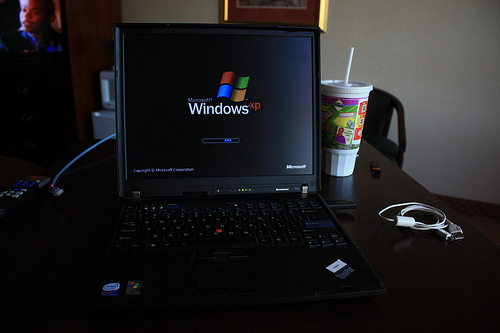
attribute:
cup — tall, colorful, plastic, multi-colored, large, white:
[326, 44, 367, 178]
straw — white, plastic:
[341, 47, 356, 80]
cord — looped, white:
[381, 205, 462, 243]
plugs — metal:
[445, 233, 461, 241]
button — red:
[215, 229, 222, 234]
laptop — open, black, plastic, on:
[84, 26, 386, 302]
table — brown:
[3, 139, 499, 330]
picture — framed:
[240, 2, 306, 7]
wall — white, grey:
[335, 1, 493, 200]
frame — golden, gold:
[223, 4, 329, 33]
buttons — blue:
[12, 178, 35, 189]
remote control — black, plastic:
[4, 169, 51, 212]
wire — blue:
[50, 126, 115, 183]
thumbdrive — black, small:
[370, 161, 381, 179]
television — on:
[4, 2, 70, 56]